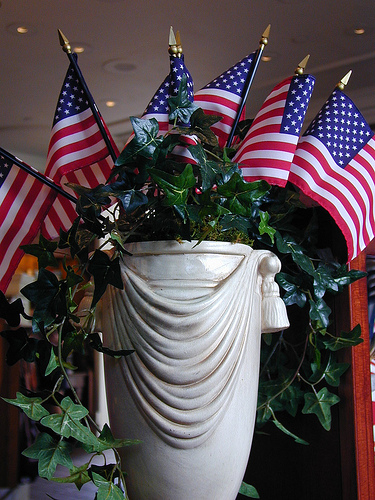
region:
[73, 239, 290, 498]
the large white planter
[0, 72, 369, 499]
the plant in the planter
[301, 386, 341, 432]
the leaf on the plant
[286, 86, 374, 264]
the american flag in the plant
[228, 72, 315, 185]
the american flag in the plant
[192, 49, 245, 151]
the american flag in the plant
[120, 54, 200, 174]
the american flag in the plant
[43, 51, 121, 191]
the american flag in the plant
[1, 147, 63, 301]
the american flag in the plant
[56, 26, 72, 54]
the point gold end on the flag pole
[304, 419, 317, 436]
part of a leaf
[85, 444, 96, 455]
part of a twig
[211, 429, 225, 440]
edge of a vase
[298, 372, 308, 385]
edge of a leaf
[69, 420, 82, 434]
part of a leaf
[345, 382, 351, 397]
edge of a door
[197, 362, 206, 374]
edge of a vase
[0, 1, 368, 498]
American flags in a vase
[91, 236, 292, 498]
a white decorated vase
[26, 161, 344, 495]
a green plant in a vase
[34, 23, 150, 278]
an American flag in a vase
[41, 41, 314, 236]
green leaves in front American flags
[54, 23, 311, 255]
American flags behind green leaves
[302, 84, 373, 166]
white stars on blue background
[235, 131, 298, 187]
red and white stripes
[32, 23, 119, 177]
an American flag on a black pole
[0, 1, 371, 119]
a white ceiling with lights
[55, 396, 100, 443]
Green leaf on vine.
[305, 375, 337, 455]
Green leaf on vine.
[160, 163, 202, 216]
Green leaf on vine.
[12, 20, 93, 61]
Lights on white ceiling.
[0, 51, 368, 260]
six red,white and blue flags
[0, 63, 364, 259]
flags stuck into a flower pot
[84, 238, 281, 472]
a white flower pot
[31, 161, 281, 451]
green vine in a flower pot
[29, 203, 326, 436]
fake green vine in a flower pot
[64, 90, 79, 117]
white stars on a flag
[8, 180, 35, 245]
red stripes on a flag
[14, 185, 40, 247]
white stripes on a flag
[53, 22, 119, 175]
small flag pole with gold tip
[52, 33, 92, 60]
recessed lighting on a cieling